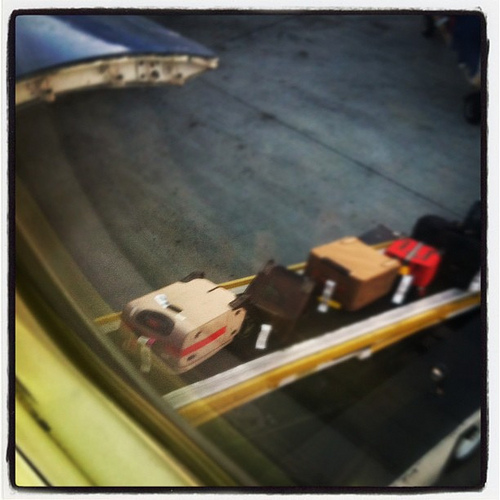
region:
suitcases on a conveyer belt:
[100, 187, 466, 402]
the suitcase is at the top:
[128, 251, 279, 363]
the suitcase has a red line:
[110, 257, 241, 366]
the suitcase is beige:
[107, 235, 247, 371]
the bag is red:
[377, 222, 444, 300]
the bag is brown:
[232, 250, 329, 337]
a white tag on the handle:
[107, 322, 177, 380]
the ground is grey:
[174, 80, 406, 205]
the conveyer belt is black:
[96, 316, 420, 396]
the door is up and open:
[0, 0, 274, 250]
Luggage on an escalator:
[43, 95, 488, 442]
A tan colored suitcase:
[122, 257, 232, 363]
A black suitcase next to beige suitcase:
[240, 256, 307, 346]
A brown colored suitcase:
[306, 220, 391, 311]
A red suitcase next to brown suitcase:
[386, 226, 440, 289]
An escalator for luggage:
[111, 244, 499, 370]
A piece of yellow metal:
[55, 373, 147, 484]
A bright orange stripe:
[148, 334, 233, 356]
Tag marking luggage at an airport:
[238, 311, 275, 356]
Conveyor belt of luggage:
[108, 151, 478, 386]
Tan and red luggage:
[102, 272, 248, 378]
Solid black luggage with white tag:
[238, 263, 314, 370]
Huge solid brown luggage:
[303, 229, 393, 323]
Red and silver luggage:
[383, 226, 435, 301]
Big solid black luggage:
[423, 215, 483, 287]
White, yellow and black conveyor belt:
[83, 233, 493, 435]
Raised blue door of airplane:
[0, 0, 233, 103]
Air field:
[15, 14, 477, 317]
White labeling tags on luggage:
[104, 226, 433, 391]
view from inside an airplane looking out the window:
[10, 11, 477, 485]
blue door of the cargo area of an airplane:
[12, 15, 230, 118]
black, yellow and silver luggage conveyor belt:
[82, 197, 490, 428]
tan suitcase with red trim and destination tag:
[108, 270, 249, 375]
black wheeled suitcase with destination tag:
[223, 257, 322, 354]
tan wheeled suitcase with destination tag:
[290, 232, 407, 327]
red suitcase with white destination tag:
[377, 232, 447, 301]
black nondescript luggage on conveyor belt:
[402, 208, 477, 299]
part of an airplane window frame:
[0, 299, 232, 481]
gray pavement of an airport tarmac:
[102, 84, 450, 212]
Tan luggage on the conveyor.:
[119, 260, 251, 379]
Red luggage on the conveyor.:
[382, 233, 441, 286]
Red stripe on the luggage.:
[122, 319, 234, 364]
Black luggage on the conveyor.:
[238, 255, 313, 347]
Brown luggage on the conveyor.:
[307, 232, 397, 312]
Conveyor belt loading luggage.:
[70, 213, 496, 426]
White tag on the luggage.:
[252, 323, 274, 355]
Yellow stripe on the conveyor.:
[147, 290, 493, 429]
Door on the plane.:
[7, 2, 216, 112]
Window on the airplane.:
[10, 8, 480, 495]